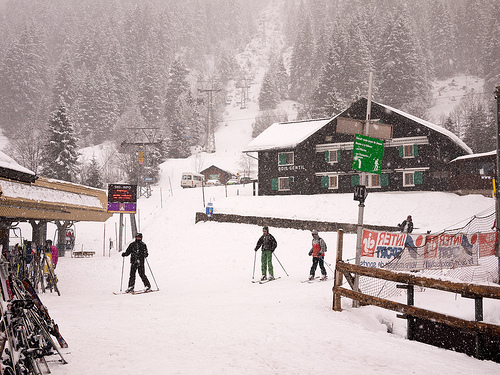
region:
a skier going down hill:
[111, 233, 158, 298]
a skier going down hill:
[246, 219, 290, 287]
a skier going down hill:
[300, 230, 331, 288]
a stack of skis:
[3, 262, 60, 367]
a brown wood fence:
[318, 262, 499, 342]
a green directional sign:
[346, 133, 388, 180]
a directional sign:
[103, 179, 137, 219]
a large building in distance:
[242, 104, 492, 198]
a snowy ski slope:
[185, 9, 286, 176]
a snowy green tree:
[38, 99, 83, 183]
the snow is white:
[191, 335, 261, 367]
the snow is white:
[217, 306, 267, 372]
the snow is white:
[223, 284, 290, 368]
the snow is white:
[232, 323, 297, 373]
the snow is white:
[284, 357, 301, 369]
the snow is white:
[199, 295, 246, 348]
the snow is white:
[187, 276, 251, 357]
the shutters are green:
[314, 171, 331, 191]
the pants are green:
[259, 247, 278, 285]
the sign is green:
[325, 112, 390, 184]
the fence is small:
[330, 222, 489, 341]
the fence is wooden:
[326, 244, 480, 344]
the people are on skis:
[122, 226, 326, 309]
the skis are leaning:
[10, 248, 66, 372]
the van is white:
[167, 165, 204, 195]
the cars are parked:
[204, 169, 260, 190]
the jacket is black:
[252, 233, 280, 253]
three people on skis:
[103, 230, 329, 302]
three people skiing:
[111, 229, 327, 299]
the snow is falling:
[99, 32, 281, 147]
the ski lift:
[110, 119, 161, 199]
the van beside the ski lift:
[174, 168, 206, 190]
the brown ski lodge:
[241, 85, 491, 202]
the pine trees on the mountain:
[17, 22, 148, 165]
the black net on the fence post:
[347, 216, 493, 283]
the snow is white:
[189, 310, 296, 373]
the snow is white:
[232, 332, 248, 363]